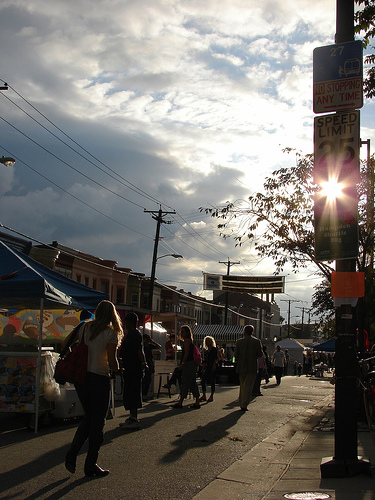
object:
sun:
[313, 163, 354, 229]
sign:
[312, 110, 361, 185]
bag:
[67, 338, 89, 386]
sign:
[329, 270, 364, 299]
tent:
[0, 237, 106, 316]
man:
[233, 324, 262, 410]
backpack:
[192, 341, 203, 365]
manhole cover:
[280, 490, 329, 500]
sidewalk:
[0, 375, 374, 498]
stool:
[156, 368, 174, 398]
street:
[0, 372, 374, 499]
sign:
[12, 306, 75, 341]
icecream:
[42, 310, 64, 336]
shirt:
[272, 351, 285, 367]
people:
[170, 325, 202, 408]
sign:
[312, 42, 363, 84]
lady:
[64, 300, 122, 479]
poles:
[148, 213, 161, 302]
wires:
[0, 145, 155, 241]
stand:
[196, 334, 225, 402]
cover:
[197, 323, 254, 337]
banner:
[201, 272, 288, 294]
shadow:
[158, 406, 250, 466]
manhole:
[285, 487, 325, 500]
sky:
[0, 0, 374, 328]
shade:
[0, 399, 82, 445]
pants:
[234, 362, 255, 411]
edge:
[188, 401, 317, 500]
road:
[0, 373, 333, 497]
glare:
[310, 155, 360, 231]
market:
[0, 233, 374, 498]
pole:
[334, 334, 358, 476]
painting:
[10, 311, 78, 340]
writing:
[342, 275, 357, 287]